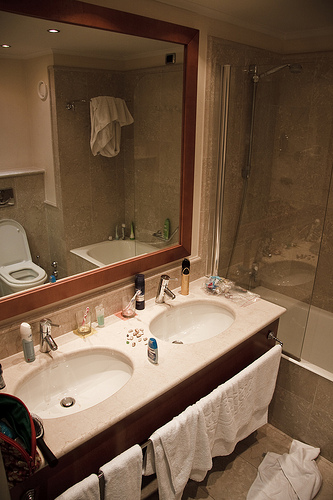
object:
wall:
[120, 61, 183, 244]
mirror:
[0, 12, 188, 303]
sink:
[149, 298, 233, 346]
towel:
[90, 98, 135, 160]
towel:
[246, 437, 323, 499]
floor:
[181, 424, 333, 499]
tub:
[69, 236, 164, 268]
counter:
[0, 274, 286, 499]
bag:
[0, 392, 37, 474]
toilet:
[0, 218, 48, 298]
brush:
[123, 288, 142, 310]